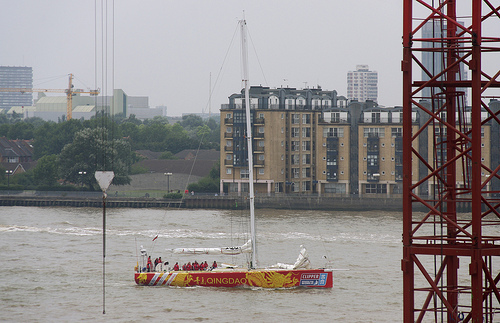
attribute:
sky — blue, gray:
[2, 3, 500, 114]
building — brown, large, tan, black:
[216, 80, 500, 198]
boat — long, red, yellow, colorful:
[133, 14, 336, 291]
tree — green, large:
[56, 124, 132, 195]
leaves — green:
[58, 123, 133, 185]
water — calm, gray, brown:
[2, 202, 500, 322]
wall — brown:
[217, 107, 489, 190]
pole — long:
[236, 21, 260, 265]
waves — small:
[1, 219, 402, 248]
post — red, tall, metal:
[395, 1, 499, 322]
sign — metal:
[94, 170, 117, 191]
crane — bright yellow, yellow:
[1, 72, 103, 119]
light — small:
[163, 171, 175, 191]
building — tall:
[343, 60, 383, 101]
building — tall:
[414, 16, 474, 105]